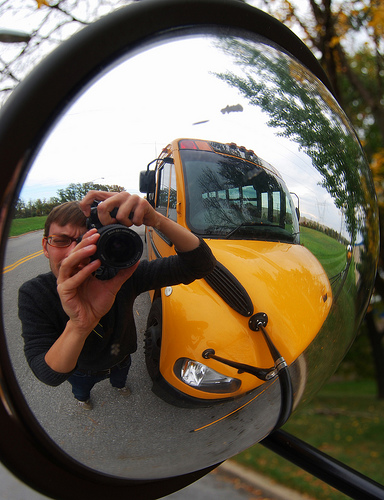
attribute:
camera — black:
[81, 208, 145, 281]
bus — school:
[136, 136, 334, 406]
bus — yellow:
[119, 141, 337, 404]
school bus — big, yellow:
[138, 135, 336, 408]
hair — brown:
[47, 203, 109, 228]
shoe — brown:
[76, 393, 94, 417]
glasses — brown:
[40, 229, 74, 249]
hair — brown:
[43, 201, 93, 226]